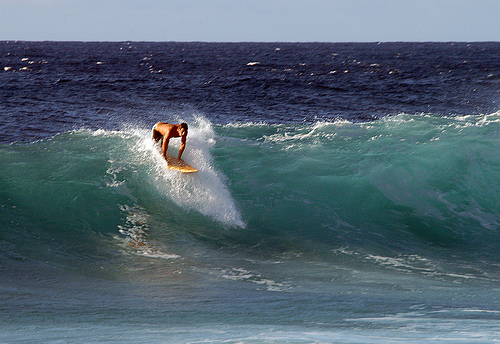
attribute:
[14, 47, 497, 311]
ocean — blue, dark, green, big, deep, white, wavy, aqua, large, splashing, shiny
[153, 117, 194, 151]
man — surfing, sufring, white, tan, swimming, skinny, riding board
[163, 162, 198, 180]
board — yellow, long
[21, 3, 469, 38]
sky — blue